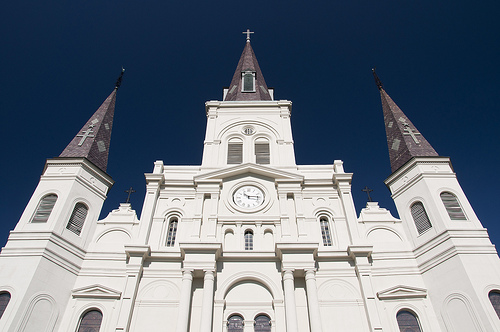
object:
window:
[241, 71, 259, 95]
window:
[242, 226, 256, 250]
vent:
[239, 124, 256, 137]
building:
[4, 19, 494, 331]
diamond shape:
[389, 137, 403, 151]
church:
[6, 26, 498, 330]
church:
[62, 63, 386, 321]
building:
[115, 120, 405, 324]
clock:
[222, 175, 285, 215]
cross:
[396, 122, 423, 145]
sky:
[100, 5, 196, 79]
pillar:
[177, 272, 197, 331]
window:
[405, 201, 439, 235]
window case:
[237, 227, 257, 253]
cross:
[76, 124, 98, 147]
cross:
[236, 24, 261, 45]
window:
[433, 188, 470, 224]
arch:
[214, 279, 275, 329]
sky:
[53, 1, 498, 171]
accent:
[368, 279, 481, 319]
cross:
[111, 180, 147, 208]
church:
[54, 85, 462, 307]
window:
[234, 66, 259, 96]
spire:
[222, 23, 283, 105]